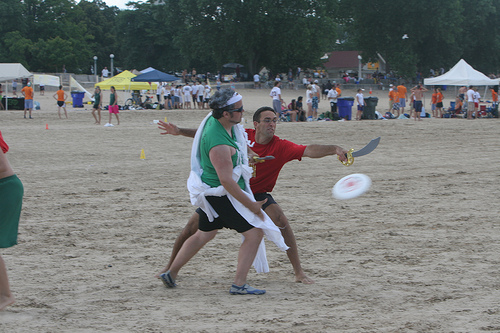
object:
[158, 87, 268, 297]
man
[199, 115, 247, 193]
shirt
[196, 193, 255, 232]
shorts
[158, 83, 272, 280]
toilet paper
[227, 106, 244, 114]
glasses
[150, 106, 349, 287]
man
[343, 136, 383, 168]
knife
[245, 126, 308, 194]
shirt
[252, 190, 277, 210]
shorts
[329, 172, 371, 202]
frisbee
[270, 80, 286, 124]
people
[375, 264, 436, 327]
sand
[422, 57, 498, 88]
tent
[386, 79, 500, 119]
crowd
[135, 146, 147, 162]
cone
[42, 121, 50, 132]
cone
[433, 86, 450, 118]
people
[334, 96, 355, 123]
trash cans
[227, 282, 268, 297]
shoe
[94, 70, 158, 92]
tent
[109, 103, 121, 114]
shorts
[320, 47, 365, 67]
roof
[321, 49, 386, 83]
building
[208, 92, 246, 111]
headband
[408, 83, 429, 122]
person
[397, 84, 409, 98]
shirt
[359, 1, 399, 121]
background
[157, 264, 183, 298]
feet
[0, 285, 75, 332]
area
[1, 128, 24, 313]
person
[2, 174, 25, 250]
shorts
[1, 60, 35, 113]
structure